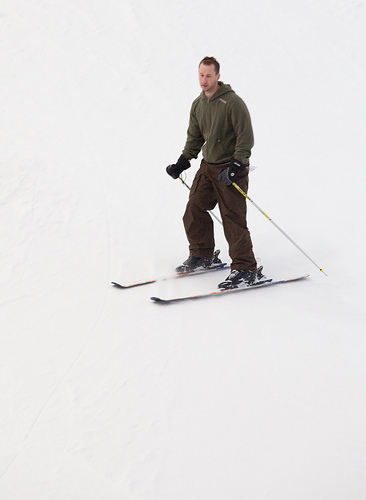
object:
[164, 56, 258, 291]
man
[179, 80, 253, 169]
man sweatshirt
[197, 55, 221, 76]
hair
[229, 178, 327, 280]
pole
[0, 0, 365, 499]
snow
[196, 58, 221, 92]
head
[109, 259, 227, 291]
ski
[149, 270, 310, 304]
ski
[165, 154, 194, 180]
glove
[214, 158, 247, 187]
glove